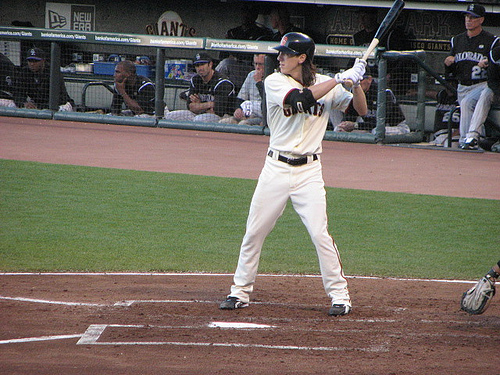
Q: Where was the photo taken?
A: It was taken at the field.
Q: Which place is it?
A: It is a field.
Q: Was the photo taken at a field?
A: Yes, it was taken in a field.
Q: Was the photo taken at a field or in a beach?
A: It was taken at a field.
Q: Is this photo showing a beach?
A: No, the picture is showing a field.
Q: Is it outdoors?
A: Yes, it is outdoors.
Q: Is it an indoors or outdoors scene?
A: It is outdoors.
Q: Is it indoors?
A: No, it is outdoors.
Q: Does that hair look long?
A: Yes, the hair is long.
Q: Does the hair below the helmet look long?
A: Yes, the hair is long.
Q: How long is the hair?
A: The hair is long.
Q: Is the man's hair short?
A: No, the hair is long.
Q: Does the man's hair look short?
A: No, the hair is long.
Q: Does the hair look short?
A: No, the hair is long.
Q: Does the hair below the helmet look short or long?
A: The hair is long.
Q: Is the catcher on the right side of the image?
A: Yes, the catcher is on the right of the image.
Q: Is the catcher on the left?
A: No, the catcher is on the right of the image.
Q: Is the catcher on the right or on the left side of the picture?
A: The catcher is on the right of the image.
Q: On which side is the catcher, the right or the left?
A: The catcher is on the right of the image.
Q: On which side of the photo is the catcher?
A: The catcher is on the right of the image.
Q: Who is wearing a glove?
A: The catcher is wearing a glove.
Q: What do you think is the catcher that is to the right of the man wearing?
A: The catcher is wearing a glove.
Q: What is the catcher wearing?
A: The catcher is wearing a glove.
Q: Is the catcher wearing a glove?
A: Yes, the catcher is wearing a glove.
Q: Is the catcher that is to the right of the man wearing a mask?
A: No, the catcher is wearing a glove.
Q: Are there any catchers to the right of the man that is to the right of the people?
A: Yes, there is a catcher to the right of the man.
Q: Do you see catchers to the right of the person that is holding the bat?
A: Yes, there is a catcher to the right of the man.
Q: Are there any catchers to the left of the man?
A: No, the catcher is to the right of the man.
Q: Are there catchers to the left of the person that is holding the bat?
A: No, the catcher is to the right of the man.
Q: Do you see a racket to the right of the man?
A: No, there is a catcher to the right of the man.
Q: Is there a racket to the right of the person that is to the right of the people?
A: No, there is a catcher to the right of the man.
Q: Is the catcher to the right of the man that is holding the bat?
A: Yes, the catcher is to the right of the man.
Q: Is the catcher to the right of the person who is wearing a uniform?
A: Yes, the catcher is to the right of the man.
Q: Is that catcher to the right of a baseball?
A: No, the catcher is to the right of the man.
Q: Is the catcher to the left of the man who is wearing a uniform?
A: No, the catcher is to the right of the man.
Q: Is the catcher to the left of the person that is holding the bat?
A: No, the catcher is to the right of the man.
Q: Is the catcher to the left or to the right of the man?
A: The catcher is to the right of the man.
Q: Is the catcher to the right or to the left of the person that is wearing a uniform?
A: The catcher is to the right of the man.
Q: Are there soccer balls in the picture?
A: No, there are no soccer balls.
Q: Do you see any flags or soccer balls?
A: No, there are no soccer balls or flags.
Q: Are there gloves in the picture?
A: Yes, there are gloves.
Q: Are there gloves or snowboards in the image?
A: Yes, there are gloves.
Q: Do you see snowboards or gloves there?
A: Yes, there are gloves.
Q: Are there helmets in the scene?
A: Yes, there is a helmet.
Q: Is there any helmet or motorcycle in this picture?
A: Yes, there is a helmet.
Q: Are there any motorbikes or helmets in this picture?
A: Yes, there is a helmet.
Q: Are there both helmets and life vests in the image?
A: No, there is a helmet but no life jackets.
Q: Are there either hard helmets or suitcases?
A: Yes, there is a hard helmet.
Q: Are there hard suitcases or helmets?
A: Yes, there is a hard helmet.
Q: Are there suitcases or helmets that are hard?
A: Yes, the helmet is hard.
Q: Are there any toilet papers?
A: No, there are no toilet papers.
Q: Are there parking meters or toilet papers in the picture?
A: No, there are no toilet papers or parking meters.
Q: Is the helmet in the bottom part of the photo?
A: No, the helmet is in the top of the image.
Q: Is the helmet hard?
A: Yes, the helmet is hard.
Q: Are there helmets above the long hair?
A: Yes, there is a helmet above the hair.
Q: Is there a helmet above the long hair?
A: Yes, there is a helmet above the hair.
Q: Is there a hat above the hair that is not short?
A: No, there is a helmet above the hair.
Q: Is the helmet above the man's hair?
A: Yes, the helmet is above the hair.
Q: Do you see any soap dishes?
A: No, there are no soap dishes.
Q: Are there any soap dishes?
A: No, there are no soap dishes.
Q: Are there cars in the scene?
A: No, there are no cars.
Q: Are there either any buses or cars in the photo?
A: No, there are no cars or buses.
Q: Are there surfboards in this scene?
A: No, there are no surfboards.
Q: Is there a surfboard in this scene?
A: No, there are no surfboards.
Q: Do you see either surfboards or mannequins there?
A: No, there are no surfboards or mannequins.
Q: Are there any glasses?
A: No, there are no glasses.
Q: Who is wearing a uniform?
A: The man is wearing a uniform.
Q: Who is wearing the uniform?
A: The man is wearing a uniform.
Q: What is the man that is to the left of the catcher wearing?
A: The man is wearing a uniform.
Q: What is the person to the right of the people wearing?
A: The man is wearing a uniform.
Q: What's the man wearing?
A: The man is wearing a uniform.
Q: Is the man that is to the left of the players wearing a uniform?
A: Yes, the man is wearing a uniform.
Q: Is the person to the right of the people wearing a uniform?
A: Yes, the man is wearing a uniform.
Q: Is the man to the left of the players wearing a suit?
A: No, the man is wearing a uniform.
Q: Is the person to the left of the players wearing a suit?
A: No, the man is wearing a uniform.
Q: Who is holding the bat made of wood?
A: The man is holding the bat.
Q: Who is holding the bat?
A: The man is holding the bat.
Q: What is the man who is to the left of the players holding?
A: The man is holding the bat.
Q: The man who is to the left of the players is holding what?
A: The man is holding the bat.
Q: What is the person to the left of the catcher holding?
A: The man is holding the bat.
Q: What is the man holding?
A: The man is holding the bat.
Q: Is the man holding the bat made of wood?
A: Yes, the man is holding the bat.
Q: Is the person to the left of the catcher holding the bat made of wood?
A: Yes, the man is holding the bat.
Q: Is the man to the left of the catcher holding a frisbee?
A: No, the man is holding the bat.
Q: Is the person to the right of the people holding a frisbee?
A: No, the man is holding the bat.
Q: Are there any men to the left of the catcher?
A: Yes, there is a man to the left of the catcher.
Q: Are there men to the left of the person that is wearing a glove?
A: Yes, there is a man to the left of the catcher.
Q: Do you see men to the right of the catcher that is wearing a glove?
A: No, the man is to the left of the catcher.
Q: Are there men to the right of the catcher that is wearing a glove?
A: No, the man is to the left of the catcher.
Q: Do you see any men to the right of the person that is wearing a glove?
A: No, the man is to the left of the catcher.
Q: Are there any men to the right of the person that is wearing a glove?
A: No, the man is to the left of the catcher.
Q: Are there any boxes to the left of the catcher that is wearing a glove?
A: No, there is a man to the left of the catcher.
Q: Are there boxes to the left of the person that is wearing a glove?
A: No, there is a man to the left of the catcher.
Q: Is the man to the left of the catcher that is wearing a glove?
A: Yes, the man is to the left of the catcher.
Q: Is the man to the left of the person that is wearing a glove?
A: Yes, the man is to the left of the catcher.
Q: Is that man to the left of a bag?
A: No, the man is to the left of the catcher.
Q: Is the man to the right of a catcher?
A: No, the man is to the left of a catcher.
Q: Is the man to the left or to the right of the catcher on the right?
A: The man is to the left of the catcher.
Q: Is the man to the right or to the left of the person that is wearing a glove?
A: The man is to the left of the catcher.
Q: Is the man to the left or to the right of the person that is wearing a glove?
A: The man is to the left of the catcher.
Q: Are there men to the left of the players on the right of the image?
A: Yes, there is a man to the left of the players.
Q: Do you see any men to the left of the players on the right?
A: Yes, there is a man to the left of the players.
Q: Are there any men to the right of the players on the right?
A: No, the man is to the left of the players.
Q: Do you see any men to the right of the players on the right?
A: No, the man is to the left of the players.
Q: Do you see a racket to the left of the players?
A: No, there is a man to the left of the players.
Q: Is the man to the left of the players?
A: Yes, the man is to the left of the players.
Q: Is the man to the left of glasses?
A: No, the man is to the left of the players.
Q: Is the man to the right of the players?
A: No, the man is to the left of the players.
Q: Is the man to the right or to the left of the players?
A: The man is to the left of the players.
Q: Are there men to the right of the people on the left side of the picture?
A: Yes, there is a man to the right of the people.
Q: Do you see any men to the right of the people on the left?
A: Yes, there is a man to the right of the people.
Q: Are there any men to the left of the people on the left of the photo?
A: No, the man is to the right of the people.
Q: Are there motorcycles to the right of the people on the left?
A: No, there is a man to the right of the people.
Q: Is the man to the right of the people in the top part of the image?
A: Yes, the man is to the right of the people.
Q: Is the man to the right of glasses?
A: No, the man is to the right of the people.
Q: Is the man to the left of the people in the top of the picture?
A: No, the man is to the right of the people.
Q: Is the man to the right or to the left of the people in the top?
A: The man is to the right of the people.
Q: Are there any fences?
A: Yes, there is a fence.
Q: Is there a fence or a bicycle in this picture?
A: Yes, there is a fence.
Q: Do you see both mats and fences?
A: No, there is a fence but no mats.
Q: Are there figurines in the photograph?
A: No, there are no figurines.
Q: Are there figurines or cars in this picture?
A: No, there are no figurines or cars.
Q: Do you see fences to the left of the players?
A: Yes, there is a fence to the left of the players.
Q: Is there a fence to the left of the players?
A: Yes, there is a fence to the left of the players.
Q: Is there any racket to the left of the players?
A: No, there is a fence to the left of the players.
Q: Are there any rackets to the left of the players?
A: No, there is a fence to the left of the players.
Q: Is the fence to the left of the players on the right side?
A: Yes, the fence is to the left of the players.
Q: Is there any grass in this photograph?
A: Yes, there is grass.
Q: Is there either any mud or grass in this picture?
A: Yes, there is grass.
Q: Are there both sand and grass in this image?
A: No, there is grass but no sand.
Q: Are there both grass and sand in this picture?
A: No, there is grass but no sand.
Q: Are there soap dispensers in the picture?
A: No, there are no soap dispensers.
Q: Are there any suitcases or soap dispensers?
A: No, there are no soap dispensers or suitcases.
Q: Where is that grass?
A: The grass is in the field.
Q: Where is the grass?
A: The grass is in the field.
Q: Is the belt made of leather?
A: Yes, the belt is made of leather.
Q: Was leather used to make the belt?
A: Yes, the belt is made of leather.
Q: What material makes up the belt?
A: The belt is made of leather.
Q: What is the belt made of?
A: The belt is made of leather.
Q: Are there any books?
A: No, there are no books.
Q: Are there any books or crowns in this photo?
A: No, there are no books or crowns.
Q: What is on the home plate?
A: The dirt is on the home plate.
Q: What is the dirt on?
A: The dirt is on the home plate.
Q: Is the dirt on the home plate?
A: Yes, the dirt is on the home plate.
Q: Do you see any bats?
A: Yes, there is a bat.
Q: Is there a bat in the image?
A: Yes, there is a bat.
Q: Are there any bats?
A: Yes, there is a bat.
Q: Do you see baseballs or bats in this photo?
A: Yes, there is a bat.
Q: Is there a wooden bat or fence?
A: Yes, there is a wood bat.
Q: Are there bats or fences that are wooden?
A: Yes, the bat is wooden.